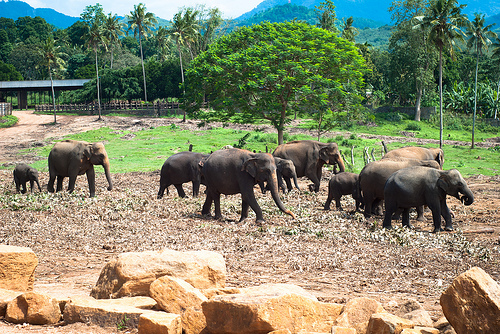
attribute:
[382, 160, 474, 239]
elephant — walking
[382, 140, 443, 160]
elephant — walking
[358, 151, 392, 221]
elephant — walking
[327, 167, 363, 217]
elephant — walking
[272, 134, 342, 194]
elephant — walking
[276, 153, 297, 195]
elephant — walking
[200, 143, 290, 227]
elephant — walking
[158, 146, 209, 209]
elephant — walking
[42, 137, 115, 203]
elephant — walking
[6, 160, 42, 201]
elephant — walking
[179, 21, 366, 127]
leaves — green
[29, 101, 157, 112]
fence — wooden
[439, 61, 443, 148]
trunk — thin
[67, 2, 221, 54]
leaves — green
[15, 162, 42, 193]
elephant — baby, walking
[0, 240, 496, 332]
rocks — brown, large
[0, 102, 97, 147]
dirt — brown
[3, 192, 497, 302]
grass — dry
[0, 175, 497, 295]
grass — dry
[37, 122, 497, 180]
pasture — green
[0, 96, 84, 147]
path — part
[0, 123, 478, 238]
elephant — herd, in captivity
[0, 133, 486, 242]
elephant — herd, in captivity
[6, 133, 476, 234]
elephant — herd, in captivity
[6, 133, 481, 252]
elephant — in captivity, herd